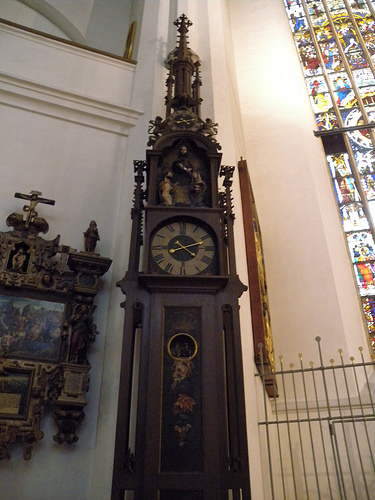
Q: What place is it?
A: It is a church.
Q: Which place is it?
A: It is a church.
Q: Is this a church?
A: Yes, it is a church.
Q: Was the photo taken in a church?
A: Yes, it was taken in a church.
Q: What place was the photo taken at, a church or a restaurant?
A: It was taken at a church.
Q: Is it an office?
A: No, it is a church.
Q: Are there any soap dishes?
A: No, there are no soap dishes.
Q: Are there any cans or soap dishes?
A: No, there are no soap dishes or cans.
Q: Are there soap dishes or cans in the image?
A: No, there are no soap dishes or cans.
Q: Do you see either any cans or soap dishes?
A: No, there are no soap dishes or cans.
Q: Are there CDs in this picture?
A: No, there are no cds.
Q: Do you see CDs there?
A: No, there are no cds.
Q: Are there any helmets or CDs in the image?
A: No, there are no CDs or helmets.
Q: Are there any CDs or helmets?
A: No, there are no CDs or helmets.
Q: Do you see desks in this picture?
A: No, there are no desks.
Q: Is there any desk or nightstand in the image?
A: No, there are no desks or nightstands.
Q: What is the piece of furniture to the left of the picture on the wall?
A: The piece of furniture is a shelf.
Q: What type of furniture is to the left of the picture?
A: The piece of furniture is a shelf.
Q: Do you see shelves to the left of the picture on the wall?
A: Yes, there is a shelf to the left of the picture.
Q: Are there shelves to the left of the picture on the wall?
A: Yes, there is a shelf to the left of the picture.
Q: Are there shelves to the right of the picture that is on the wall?
A: No, the shelf is to the left of the picture.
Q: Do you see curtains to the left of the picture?
A: No, there is a shelf to the left of the picture.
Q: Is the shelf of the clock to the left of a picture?
A: Yes, the shelf is to the left of a picture.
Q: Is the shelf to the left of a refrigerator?
A: No, the shelf is to the left of a picture.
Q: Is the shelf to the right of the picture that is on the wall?
A: No, the shelf is to the left of the picture.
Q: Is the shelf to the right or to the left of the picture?
A: The shelf is to the left of the picture.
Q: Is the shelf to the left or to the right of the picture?
A: The shelf is to the left of the picture.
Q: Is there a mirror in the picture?
A: No, there are no mirrors.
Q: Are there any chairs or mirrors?
A: No, there are no mirrors or chairs.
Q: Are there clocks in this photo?
A: Yes, there is a clock.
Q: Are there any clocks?
A: Yes, there is a clock.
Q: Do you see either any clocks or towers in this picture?
A: Yes, there is a clock.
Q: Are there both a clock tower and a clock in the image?
A: No, there is a clock but no clock towers.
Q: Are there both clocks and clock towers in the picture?
A: No, there is a clock but no clock towers.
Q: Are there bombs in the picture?
A: No, there are no bombs.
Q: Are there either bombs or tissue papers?
A: No, there are no bombs or tissue papers.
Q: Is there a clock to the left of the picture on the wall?
A: Yes, there is a clock to the left of the picture.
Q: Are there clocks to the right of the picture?
A: No, the clock is to the left of the picture.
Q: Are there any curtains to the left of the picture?
A: No, there is a clock to the left of the picture.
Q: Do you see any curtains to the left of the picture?
A: No, there is a clock to the left of the picture.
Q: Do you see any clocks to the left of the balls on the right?
A: Yes, there is a clock to the left of the balls.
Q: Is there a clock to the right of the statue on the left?
A: Yes, there is a clock to the right of the statue.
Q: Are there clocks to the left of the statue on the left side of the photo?
A: No, the clock is to the right of the statue.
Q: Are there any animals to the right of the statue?
A: No, there is a clock to the right of the statue.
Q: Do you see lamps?
A: No, there are no lamps.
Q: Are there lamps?
A: No, there are no lamps.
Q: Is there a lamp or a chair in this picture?
A: No, there are no lamps or chairs.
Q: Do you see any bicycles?
A: No, there are no bicycles.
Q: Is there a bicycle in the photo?
A: No, there are no bicycles.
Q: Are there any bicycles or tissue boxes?
A: No, there are no bicycles or tissue boxes.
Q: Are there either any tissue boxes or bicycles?
A: No, there are no bicycles or tissue boxes.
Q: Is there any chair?
A: No, there are no chairs.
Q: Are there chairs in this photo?
A: No, there are no chairs.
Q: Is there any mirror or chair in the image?
A: No, there are no chairs or mirrors.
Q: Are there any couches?
A: No, there are no couches.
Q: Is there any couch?
A: No, there are no couches.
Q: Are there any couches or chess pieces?
A: No, there are no couches or chess pieces.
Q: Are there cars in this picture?
A: No, there are no cars.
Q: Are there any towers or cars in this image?
A: No, there are no cars or towers.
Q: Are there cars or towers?
A: No, there are no cars or towers.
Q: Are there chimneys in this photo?
A: No, there are no chimneys.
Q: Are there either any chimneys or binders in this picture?
A: No, there are no chimneys or binders.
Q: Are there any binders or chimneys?
A: No, there are no chimneys or binders.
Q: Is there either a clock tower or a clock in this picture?
A: Yes, there is a clock.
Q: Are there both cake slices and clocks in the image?
A: No, there is a clock but no cake slices.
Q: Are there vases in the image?
A: No, there are no vases.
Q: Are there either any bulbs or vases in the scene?
A: No, there are no vases or bulbs.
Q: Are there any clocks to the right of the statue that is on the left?
A: Yes, there is a clock to the right of the statue.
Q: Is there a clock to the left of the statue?
A: No, the clock is to the right of the statue.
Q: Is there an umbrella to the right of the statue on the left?
A: No, there is a clock to the right of the statue.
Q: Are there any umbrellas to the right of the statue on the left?
A: No, there is a clock to the right of the statue.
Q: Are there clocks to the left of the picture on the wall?
A: Yes, there is a clock to the left of the picture.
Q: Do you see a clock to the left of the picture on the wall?
A: Yes, there is a clock to the left of the picture.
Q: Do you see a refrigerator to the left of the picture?
A: No, there is a clock to the left of the picture.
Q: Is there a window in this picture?
A: Yes, there are windows.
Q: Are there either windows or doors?
A: Yes, there are windows.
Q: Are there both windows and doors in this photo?
A: No, there are windows but no doors.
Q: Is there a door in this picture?
A: No, there are no doors.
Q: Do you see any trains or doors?
A: No, there are no doors or trains.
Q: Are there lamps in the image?
A: No, there are no lamps.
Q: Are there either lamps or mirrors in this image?
A: No, there are no lamps or mirrors.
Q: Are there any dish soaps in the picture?
A: No, there are no dish soaps.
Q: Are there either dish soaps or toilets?
A: No, there are no dish soaps or toilets.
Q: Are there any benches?
A: No, there are no benches.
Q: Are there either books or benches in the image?
A: No, there are no benches or books.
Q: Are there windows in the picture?
A: Yes, there is a window.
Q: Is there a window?
A: Yes, there is a window.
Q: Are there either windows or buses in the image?
A: Yes, there is a window.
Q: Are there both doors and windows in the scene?
A: No, there is a window but no doors.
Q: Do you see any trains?
A: No, there are no trains.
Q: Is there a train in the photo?
A: No, there are no trains.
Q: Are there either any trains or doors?
A: No, there are no trains or doors.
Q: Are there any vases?
A: No, there are no vases.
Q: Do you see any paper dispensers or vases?
A: No, there are no vases or paper dispensers.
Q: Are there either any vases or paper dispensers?
A: No, there are no vases or paper dispensers.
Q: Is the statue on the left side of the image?
A: Yes, the statue is on the left of the image.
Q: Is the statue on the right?
A: No, the statue is on the left of the image.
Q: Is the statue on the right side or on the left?
A: The statue is on the left of the image.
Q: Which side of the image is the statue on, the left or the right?
A: The statue is on the left of the image.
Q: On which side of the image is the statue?
A: The statue is on the left of the image.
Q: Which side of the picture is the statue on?
A: The statue is on the left of the image.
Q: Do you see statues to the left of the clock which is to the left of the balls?
A: Yes, there is a statue to the left of the clock.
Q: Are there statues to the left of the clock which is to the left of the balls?
A: Yes, there is a statue to the left of the clock.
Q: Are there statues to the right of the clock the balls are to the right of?
A: No, the statue is to the left of the clock.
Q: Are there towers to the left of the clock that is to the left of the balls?
A: No, there is a statue to the left of the clock.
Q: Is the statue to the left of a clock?
A: Yes, the statue is to the left of a clock.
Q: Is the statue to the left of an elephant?
A: No, the statue is to the left of a clock.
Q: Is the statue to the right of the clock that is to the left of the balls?
A: No, the statue is to the left of the clock.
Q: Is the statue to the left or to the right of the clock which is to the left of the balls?
A: The statue is to the left of the clock.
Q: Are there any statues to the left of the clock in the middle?
A: Yes, there is a statue to the left of the clock.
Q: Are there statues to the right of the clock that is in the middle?
A: No, the statue is to the left of the clock.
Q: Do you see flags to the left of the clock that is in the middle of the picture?
A: No, there is a statue to the left of the clock.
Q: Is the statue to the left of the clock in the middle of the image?
A: Yes, the statue is to the left of the clock.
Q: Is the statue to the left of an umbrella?
A: No, the statue is to the left of the clock.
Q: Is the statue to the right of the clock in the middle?
A: No, the statue is to the left of the clock.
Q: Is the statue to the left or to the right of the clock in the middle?
A: The statue is to the left of the clock.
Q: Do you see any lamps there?
A: No, there are no lamps.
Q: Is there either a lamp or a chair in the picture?
A: No, there are no lamps or chairs.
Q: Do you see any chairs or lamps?
A: No, there are no lamps or chairs.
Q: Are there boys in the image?
A: No, there are no boys.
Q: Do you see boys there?
A: No, there are no boys.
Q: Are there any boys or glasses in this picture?
A: No, there are no boys or glasses.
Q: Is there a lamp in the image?
A: No, there are no lamps.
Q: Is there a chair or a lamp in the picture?
A: No, there are no lamps or chairs.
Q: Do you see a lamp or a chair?
A: No, there are no lamps or chairs.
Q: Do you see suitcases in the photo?
A: No, there are no suitcases.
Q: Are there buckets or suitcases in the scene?
A: No, there are no suitcases or buckets.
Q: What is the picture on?
A: The picture is on the wall.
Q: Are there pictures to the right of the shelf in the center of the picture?
A: Yes, there is a picture to the right of the shelf.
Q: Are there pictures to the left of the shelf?
A: No, the picture is to the right of the shelf.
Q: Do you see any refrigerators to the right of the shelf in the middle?
A: No, there is a picture to the right of the shelf.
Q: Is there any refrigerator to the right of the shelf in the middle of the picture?
A: No, there is a picture to the right of the shelf.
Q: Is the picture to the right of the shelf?
A: Yes, the picture is to the right of the shelf.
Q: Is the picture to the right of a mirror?
A: No, the picture is to the right of the shelf.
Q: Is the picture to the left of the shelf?
A: No, the picture is to the right of the shelf.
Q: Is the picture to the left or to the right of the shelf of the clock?
A: The picture is to the right of the shelf.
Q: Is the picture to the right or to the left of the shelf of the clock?
A: The picture is to the right of the shelf.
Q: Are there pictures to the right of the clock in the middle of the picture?
A: Yes, there is a picture to the right of the clock.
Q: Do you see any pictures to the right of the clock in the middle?
A: Yes, there is a picture to the right of the clock.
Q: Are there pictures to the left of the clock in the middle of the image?
A: No, the picture is to the right of the clock.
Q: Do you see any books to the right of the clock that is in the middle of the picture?
A: No, there is a picture to the right of the clock.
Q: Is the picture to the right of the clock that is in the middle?
A: Yes, the picture is to the right of the clock.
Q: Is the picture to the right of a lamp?
A: No, the picture is to the right of the clock.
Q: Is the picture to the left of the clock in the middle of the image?
A: No, the picture is to the right of the clock.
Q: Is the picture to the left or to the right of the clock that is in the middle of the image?
A: The picture is to the right of the clock.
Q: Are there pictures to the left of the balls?
A: Yes, there is a picture to the left of the balls.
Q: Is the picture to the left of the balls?
A: Yes, the picture is to the left of the balls.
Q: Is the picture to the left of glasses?
A: No, the picture is to the left of the balls.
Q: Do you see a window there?
A: Yes, there is a window.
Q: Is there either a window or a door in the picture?
A: Yes, there is a window.